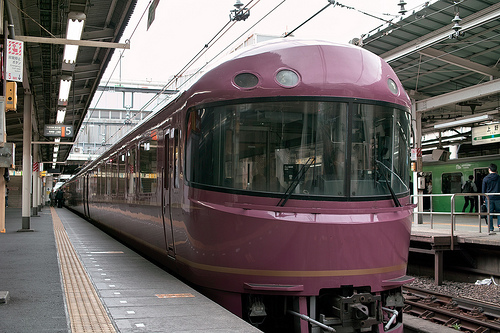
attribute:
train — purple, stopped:
[50, 38, 422, 332]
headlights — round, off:
[231, 62, 415, 104]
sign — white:
[6, 36, 26, 84]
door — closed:
[153, 120, 182, 255]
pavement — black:
[1, 201, 67, 331]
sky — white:
[96, 0, 436, 87]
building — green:
[419, 155, 500, 216]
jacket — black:
[481, 171, 499, 211]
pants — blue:
[484, 199, 499, 230]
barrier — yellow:
[50, 200, 114, 332]